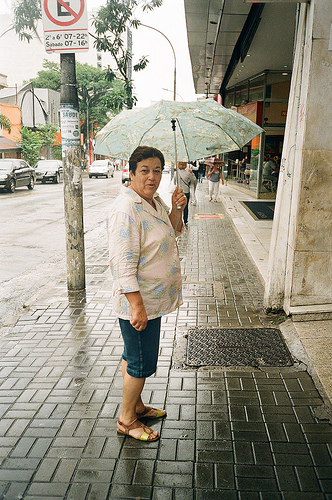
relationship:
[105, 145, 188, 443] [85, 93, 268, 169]
person hold umbrella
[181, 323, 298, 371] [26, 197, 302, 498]
man hole on sidewalk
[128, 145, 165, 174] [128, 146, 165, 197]
hair on head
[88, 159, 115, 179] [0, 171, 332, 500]
van on sidewalk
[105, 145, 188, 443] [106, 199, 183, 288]
person wears shirt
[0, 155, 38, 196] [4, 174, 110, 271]
car on road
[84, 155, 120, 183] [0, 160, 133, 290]
van on road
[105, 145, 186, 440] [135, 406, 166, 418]
person wears sandal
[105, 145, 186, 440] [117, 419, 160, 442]
person wears sandal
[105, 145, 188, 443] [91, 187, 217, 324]
person wears shirt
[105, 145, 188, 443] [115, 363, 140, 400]
person has calf muscles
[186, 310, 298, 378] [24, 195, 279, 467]
grate cover in sidewalk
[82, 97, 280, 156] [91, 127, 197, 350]
umbrella of woman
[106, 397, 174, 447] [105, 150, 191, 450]
brown sandals of woman